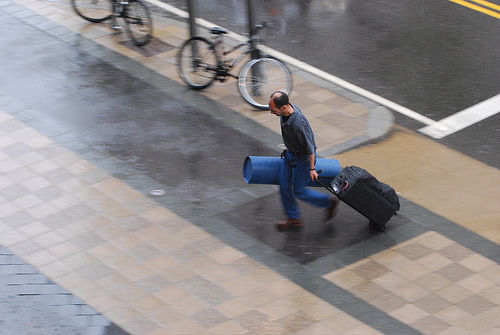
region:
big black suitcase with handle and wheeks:
[316, 166, 400, 230]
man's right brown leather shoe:
[274, 217, 301, 228]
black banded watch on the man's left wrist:
[307, 166, 317, 173]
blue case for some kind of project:
[240, 153, 342, 187]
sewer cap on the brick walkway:
[147, 185, 166, 199]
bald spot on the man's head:
[271, 87, 285, 103]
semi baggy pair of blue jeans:
[277, 150, 331, 222]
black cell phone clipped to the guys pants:
[277, 147, 288, 160]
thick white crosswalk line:
[415, 86, 499, 142]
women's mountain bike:
[174, 19, 293, 112]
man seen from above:
[266, 87, 339, 232]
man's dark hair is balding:
[267, 88, 292, 120]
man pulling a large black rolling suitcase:
[267, 88, 401, 234]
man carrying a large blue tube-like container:
[239, 91, 337, 231]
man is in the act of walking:
[266, 91, 340, 232]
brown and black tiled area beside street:
[0, 1, 495, 333]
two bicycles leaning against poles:
[52, 1, 292, 110]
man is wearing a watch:
[305, 160, 322, 176]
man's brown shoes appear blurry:
[273, 192, 341, 233]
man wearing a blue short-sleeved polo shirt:
[277, 102, 319, 159]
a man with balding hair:
[252, 89, 305, 128]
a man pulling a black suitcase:
[265, 81, 397, 248]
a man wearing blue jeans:
[265, 79, 310, 238]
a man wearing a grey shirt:
[260, 89, 320, 161]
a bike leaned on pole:
[173, 10, 284, 102]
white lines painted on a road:
[327, 48, 494, 152]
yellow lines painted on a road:
[432, 0, 497, 40]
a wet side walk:
[20, 249, 427, 308]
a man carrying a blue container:
[218, 118, 349, 194]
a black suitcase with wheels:
[321, 152, 403, 236]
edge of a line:
[181, 208, 222, 247]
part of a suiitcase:
[345, 179, 373, 217]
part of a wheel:
[373, 222, 392, 236]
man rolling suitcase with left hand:
[267, 91, 403, 234]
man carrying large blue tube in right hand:
[240, 89, 340, 231]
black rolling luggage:
[315, 164, 402, 229]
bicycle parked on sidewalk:
[176, 17, 293, 112]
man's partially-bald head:
[265, 91, 290, 117]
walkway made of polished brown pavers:
[0, 109, 381, 334]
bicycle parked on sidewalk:
[70, 0, 157, 47]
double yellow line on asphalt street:
[450, 1, 498, 21]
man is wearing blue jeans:
[277, 151, 328, 219]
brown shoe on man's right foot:
[275, 217, 304, 229]